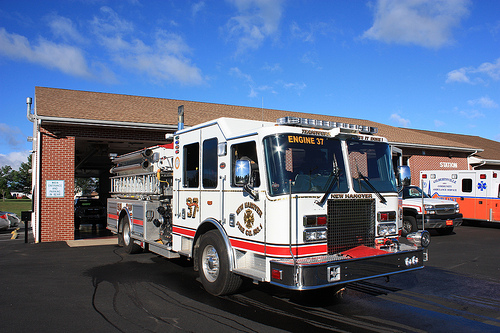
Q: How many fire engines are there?
A: One.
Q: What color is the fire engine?
A: White and red.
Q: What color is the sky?
A: Blue.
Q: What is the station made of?
A: Brick.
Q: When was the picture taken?
A: Daytime.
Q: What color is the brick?
A: Red.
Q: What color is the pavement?
A: Black.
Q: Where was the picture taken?
A: At a fire station.